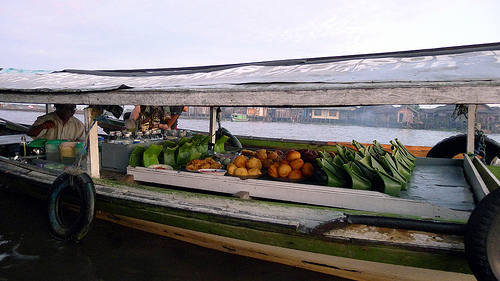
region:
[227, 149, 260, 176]
potatoes sitting on a rack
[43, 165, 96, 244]
a rubber ring is black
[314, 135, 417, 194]
leaves for sale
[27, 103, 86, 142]
a man is under a roof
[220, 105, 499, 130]
houses along the water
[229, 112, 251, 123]
a boat is in the water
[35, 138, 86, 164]
plastic containers are by a man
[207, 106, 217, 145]
a thin metal post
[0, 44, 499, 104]
an old and decrepit roof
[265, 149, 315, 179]
potatoes on a rack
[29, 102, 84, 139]
Man wearing white shirt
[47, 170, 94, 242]
Round black inner tube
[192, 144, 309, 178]
Bowls of different orange fruits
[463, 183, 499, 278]
Round black tire on boat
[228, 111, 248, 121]
Small green boat across water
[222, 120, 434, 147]
Smooth flat surface of water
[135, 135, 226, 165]
Large pieces of green seaweed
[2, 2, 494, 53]
White hazy sky with few clouds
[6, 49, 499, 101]
Gray and white roof of boat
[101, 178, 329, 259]
Chipped white and green paint on boat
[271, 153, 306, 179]
Yellow fresh fruits in the shade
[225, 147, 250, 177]
Yellow fresh fruits in the shade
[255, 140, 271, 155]
Yellow fresh fruits in the shade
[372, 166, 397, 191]
A green leaf fruit cover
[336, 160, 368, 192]
A green leaf fruit cover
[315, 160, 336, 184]
A green leaf fruit cover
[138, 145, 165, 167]
A green leaf fruit cover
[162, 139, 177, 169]
A green leaf fruit cover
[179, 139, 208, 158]
A green leaf fruit cover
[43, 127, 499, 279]
tires attached to boat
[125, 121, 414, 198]
sectioned fruit on boat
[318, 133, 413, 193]
green bags beside fruit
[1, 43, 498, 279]
boat is wood and metal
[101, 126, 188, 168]
bottles of water beside fruit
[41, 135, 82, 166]
large containers beside water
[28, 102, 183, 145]
people beside boat canopy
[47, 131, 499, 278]
tires attached to boat are black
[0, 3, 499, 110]
sky is cloudy and blue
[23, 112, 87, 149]
man is wearing button up shirt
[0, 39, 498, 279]
boat is made of metal and wood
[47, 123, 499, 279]
tires are black and rubber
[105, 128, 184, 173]
bottles of water on boat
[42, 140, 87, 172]
large plastic containers by water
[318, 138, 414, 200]
green bags by fruit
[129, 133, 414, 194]
sectioned fruit and bags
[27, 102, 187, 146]
people under boat canopy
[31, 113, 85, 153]
white button up shirt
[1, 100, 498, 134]
several buildings behind boat